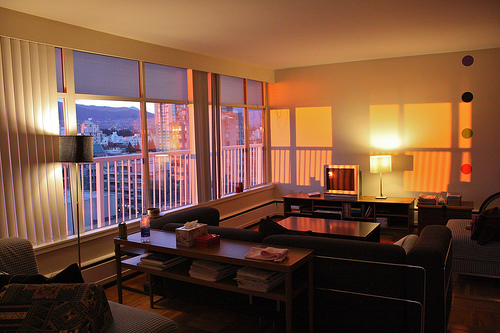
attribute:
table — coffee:
[258, 204, 388, 245]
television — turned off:
[321, 163, 358, 196]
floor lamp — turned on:
[57, 134, 97, 281]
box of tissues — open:
[174, 217, 208, 245]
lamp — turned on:
[369, 154, 392, 198]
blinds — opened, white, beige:
[1, 35, 69, 245]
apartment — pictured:
[1, 3, 500, 332]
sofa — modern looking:
[147, 204, 453, 332]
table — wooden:
[114, 227, 312, 326]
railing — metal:
[71, 142, 266, 236]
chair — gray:
[447, 192, 499, 281]